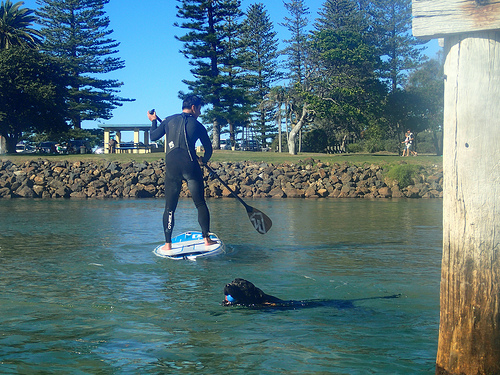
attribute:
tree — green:
[172, 3, 245, 148]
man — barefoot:
[148, 91, 219, 250]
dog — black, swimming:
[223, 275, 404, 323]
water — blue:
[1, 196, 443, 373]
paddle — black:
[147, 109, 273, 237]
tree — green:
[1, 42, 75, 154]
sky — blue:
[0, 1, 447, 153]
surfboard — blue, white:
[152, 227, 222, 260]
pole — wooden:
[436, 33, 499, 375]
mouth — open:
[217, 288, 242, 311]